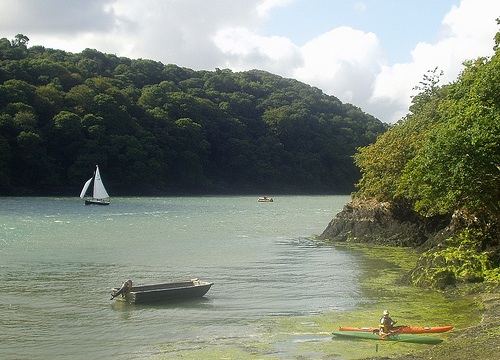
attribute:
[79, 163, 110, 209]
sailboat — white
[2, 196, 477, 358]
bay — murky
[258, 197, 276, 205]
raft — yellow, distant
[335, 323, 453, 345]
kayak — orange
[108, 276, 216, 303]
boat — empty, unmannedy, wooden, green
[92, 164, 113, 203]
drap — white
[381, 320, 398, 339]
oar — orange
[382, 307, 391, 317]
hat — white, tan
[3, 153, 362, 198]
bank — forested, foliage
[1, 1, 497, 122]
sky — cloudy, blue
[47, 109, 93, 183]
tree — lush, leafy